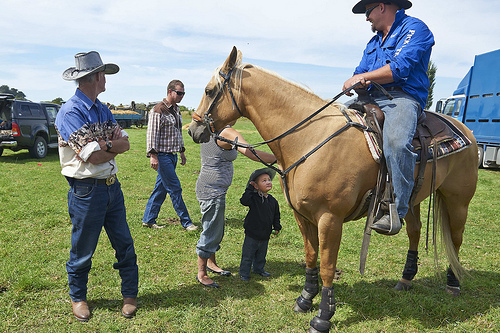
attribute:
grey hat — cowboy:
[61, 49, 121, 82]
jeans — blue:
[143, 150, 194, 226]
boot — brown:
[67, 298, 108, 323]